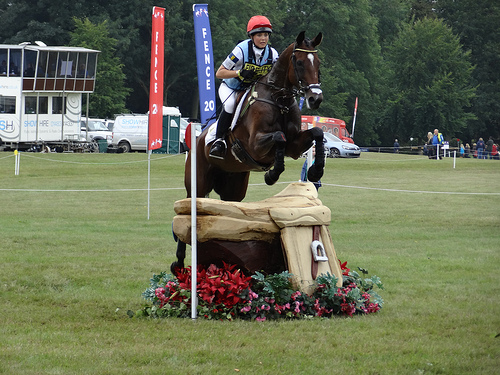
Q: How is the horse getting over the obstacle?
A: Jumping.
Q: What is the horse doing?
A: Jumping.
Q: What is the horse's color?
A: Brown.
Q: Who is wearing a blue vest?
A: The woman.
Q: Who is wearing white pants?
A: The woman.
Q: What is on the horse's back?
A: A woman.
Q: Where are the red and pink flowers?
A: On the field.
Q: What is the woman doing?
A: Jumping a horse.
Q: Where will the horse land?
A: On the grass.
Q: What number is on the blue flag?
A: Twenty.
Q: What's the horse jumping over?
A: Obstacle.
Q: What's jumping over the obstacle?
A: Horse.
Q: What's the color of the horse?
A: Brown.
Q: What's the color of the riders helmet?
A: Red.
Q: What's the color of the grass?
A: Green.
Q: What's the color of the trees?
A: Green.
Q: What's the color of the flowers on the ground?
A: Red.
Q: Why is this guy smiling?
A: He won ribbons.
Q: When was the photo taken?
A: During the day.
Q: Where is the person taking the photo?
A: In front of the horse.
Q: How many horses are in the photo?
A: One.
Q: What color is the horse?
A: Brown.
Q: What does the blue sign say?
A: Fence.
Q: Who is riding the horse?
A: Jockey.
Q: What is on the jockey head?
A: A helmet.